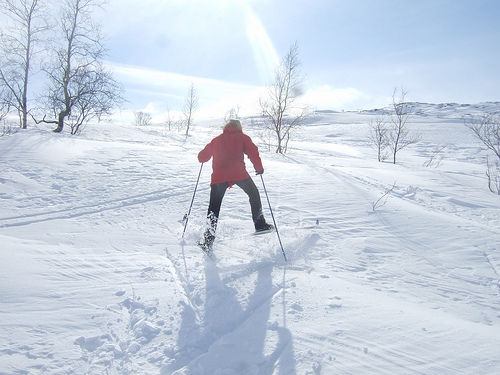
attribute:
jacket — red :
[194, 126, 259, 181]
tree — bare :
[382, 87, 418, 164]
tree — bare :
[370, 119, 390, 160]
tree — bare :
[267, 44, 307, 154]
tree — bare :
[183, 86, 200, 134]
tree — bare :
[51, 2, 114, 134]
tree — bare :
[66, 62, 116, 136]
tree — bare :
[0, 1, 46, 131]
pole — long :
[260, 174, 290, 260]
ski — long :
[208, 216, 319, 254]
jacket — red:
[197, 129, 264, 188]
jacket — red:
[197, 125, 265, 185]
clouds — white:
[2, 0, 499, 126]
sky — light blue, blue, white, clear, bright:
[2, 0, 499, 125]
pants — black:
[203, 175, 267, 242]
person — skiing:
[195, 119, 275, 253]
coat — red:
[197, 128, 262, 183]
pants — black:
[204, 176, 266, 233]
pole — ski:
[257, 165, 289, 259]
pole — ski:
[180, 160, 203, 240]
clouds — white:
[217, 7, 278, 48]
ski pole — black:
[181, 160, 201, 233]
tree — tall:
[32, 0, 130, 133]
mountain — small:
[357, 99, 483, 122]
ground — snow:
[34, 137, 477, 367]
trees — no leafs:
[269, 43, 313, 157]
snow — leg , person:
[192, 210, 221, 252]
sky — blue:
[134, 8, 402, 75]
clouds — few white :
[340, 15, 440, 77]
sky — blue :
[331, 16, 431, 65]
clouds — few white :
[164, 1, 283, 40]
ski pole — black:
[181, 160, 290, 235]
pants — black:
[202, 179, 268, 239]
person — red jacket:
[194, 132, 269, 187]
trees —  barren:
[11, 1, 431, 166]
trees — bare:
[41, 51, 112, 132]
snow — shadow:
[164, 264, 310, 364]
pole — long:
[181, 155, 201, 235]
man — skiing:
[197, 115, 270, 246]